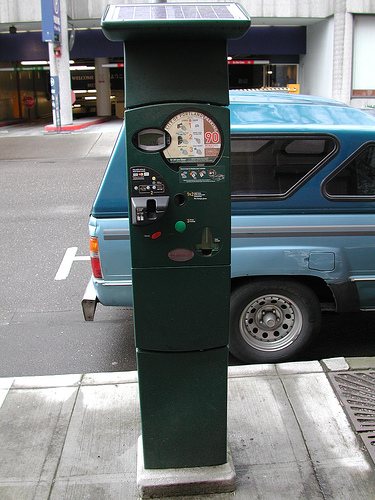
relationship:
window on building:
[258, 62, 300, 90] [19, 19, 284, 160]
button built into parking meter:
[172, 218, 186, 233] [98, 0, 252, 470]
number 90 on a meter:
[203, 128, 220, 147] [95, 6, 254, 464]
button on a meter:
[172, 218, 186, 233] [95, 6, 254, 464]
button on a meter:
[146, 227, 164, 243] [95, 6, 254, 464]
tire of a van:
[224, 282, 312, 362] [77, 101, 349, 334]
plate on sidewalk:
[330, 351, 362, 473] [1, 355, 372, 498]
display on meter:
[135, 127, 170, 152] [95, 6, 254, 464]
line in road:
[51, 239, 85, 284] [8, 154, 137, 366]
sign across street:
[40, 1, 60, 41] [10, 135, 87, 370]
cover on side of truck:
[306, 247, 338, 273] [72, 96, 355, 359]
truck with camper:
[83, 218, 345, 344] [92, 93, 374, 216]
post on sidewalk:
[96, 4, 252, 464] [1, 355, 372, 498]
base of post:
[135, 431, 235, 498] [122, 42, 228, 469]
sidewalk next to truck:
[1, 355, 372, 498] [79, 91, 374, 366]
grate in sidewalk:
[325, 367, 374, 470] [1, 355, 372, 498]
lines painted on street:
[52, 246, 88, 280] [1, 134, 373, 374]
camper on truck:
[92, 93, 374, 216] [79, 91, 374, 366]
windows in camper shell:
[229, 135, 374, 196] [92, 93, 374, 217]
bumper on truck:
[81, 275, 96, 324] [79, 91, 374, 366]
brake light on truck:
[88, 233, 102, 279] [79, 91, 374, 366]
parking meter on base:
[98, 0, 252, 470] [135, 431, 235, 498]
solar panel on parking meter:
[102, 2, 247, 23] [122, 42, 228, 470]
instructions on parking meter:
[161, 110, 221, 170] [122, 42, 228, 470]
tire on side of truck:
[224, 282, 312, 362] [79, 91, 374, 366]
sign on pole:
[40, 1, 60, 41] [47, 43, 59, 124]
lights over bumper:
[88, 235, 102, 279] [79, 273, 96, 321]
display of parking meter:
[133, 128, 171, 153] [122, 42, 228, 470]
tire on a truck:
[224, 282, 312, 362] [79, 91, 374, 366]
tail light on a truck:
[88, 235, 102, 280] [79, 91, 374, 366]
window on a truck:
[231, 136, 337, 195] [79, 91, 374, 366]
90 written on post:
[205, 130, 218, 144] [122, 42, 228, 469]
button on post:
[174, 220, 184, 232] [122, 42, 228, 469]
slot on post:
[137, 206, 162, 212] [122, 42, 228, 469]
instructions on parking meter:
[161, 110, 221, 170] [98, 0, 252, 470]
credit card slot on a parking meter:
[131, 195, 167, 227] [131, 125, 223, 329]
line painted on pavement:
[59, 242, 79, 285] [36, 307, 66, 338]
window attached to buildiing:
[28, 65, 62, 126] [11, 8, 363, 101]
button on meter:
[150, 212, 193, 246] [105, 8, 248, 495]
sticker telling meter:
[163, 109, 222, 159] [99, 38, 255, 496]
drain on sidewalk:
[326, 357, 361, 441] [3, 373, 345, 498]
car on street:
[53, 86, 363, 355] [13, 309, 96, 352]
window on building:
[231, 136, 337, 195] [311, 10, 362, 76]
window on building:
[339, 23, 363, 84] [318, 8, 357, 98]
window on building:
[363, 16, 364, 95] [356, 18, 362, 77]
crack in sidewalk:
[273, 362, 332, 494] [20, 368, 365, 497]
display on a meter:
[133, 128, 171, 153] [98, 0, 243, 487]